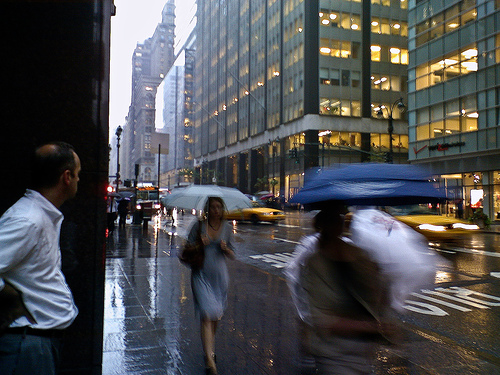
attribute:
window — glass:
[442, 116, 464, 136]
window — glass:
[424, 61, 485, 115]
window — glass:
[444, 49, 459, 79]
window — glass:
[427, 121, 445, 133]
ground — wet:
[122, 230, 499, 370]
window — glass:
[219, 102, 225, 113]